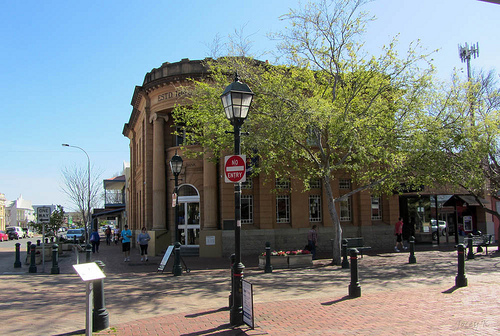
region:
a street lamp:
[221, 67, 258, 124]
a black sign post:
[223, 185, 250, 328]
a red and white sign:
[221, 151, 251, 186]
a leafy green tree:
[181, 27, 498, 204]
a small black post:
[451, 239, 474, 288]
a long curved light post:
[58, 140, 93, 233]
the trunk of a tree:
[322, 185, 347, 265]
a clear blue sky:
[0, 0, 498, 215]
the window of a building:
[271, 192, 294, 227]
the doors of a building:
[168, 186, 206, 245]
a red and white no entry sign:
[204, 145, 265, 200]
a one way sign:
[30, 204, 66, 227]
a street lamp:
[169, 142, 191, 280]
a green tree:
[266, 59, 408, 194]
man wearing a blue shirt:
[115, 222, 135, 247]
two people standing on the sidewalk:
[117, 223, 167, 258]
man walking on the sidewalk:
[384, 212, 411, 252]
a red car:
[0, 228, 12, 244]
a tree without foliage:
[58, 160, 99, 242]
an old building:
[127, 52, 375, 248]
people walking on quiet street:
[13, 185, 397, 310]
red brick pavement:
[303, 294, 418, 325]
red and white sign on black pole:
[215, 149, 254, 200]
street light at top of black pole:
[218, 75, 251, 154]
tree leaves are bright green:
[219, 13, 418, 193]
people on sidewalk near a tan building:
[115, 213, 150, 260]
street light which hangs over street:
[55, 126, 105, 217]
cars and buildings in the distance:
[6, 186, 76, 243]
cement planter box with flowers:
[249, 243, 319, 268]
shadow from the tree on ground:
[122, 270, 202, 314]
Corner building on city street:
[87, 14, 494, 293]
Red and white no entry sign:
[210, 139, 260, 197]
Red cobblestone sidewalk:
[65, 258, 492, 333]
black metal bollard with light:
[334, 237, 382, 300]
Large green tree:
[157, 11, 497, 262]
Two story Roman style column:
[142, 106, 182, 243]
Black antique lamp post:
[206, 63, 273, 329]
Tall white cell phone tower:
[440, 24, 498, 144]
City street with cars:
[0, 165, 118, 285]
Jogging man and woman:
[115, 211, 160, 276]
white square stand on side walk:
[60, 254, 107, 289]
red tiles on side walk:
[285, 295, 362, 330]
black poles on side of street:
[15, 235, 66, 277]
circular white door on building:
[170, 178, 217, 255]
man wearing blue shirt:
[103, 227, 146, 248]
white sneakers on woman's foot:
[131, 246, 166, 267]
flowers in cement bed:
[287, 244, 316, 263]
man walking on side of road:
[388, 203, 406, 254]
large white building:
[5, 187, 41, 229]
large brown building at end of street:
[115, 52, 398, 259]